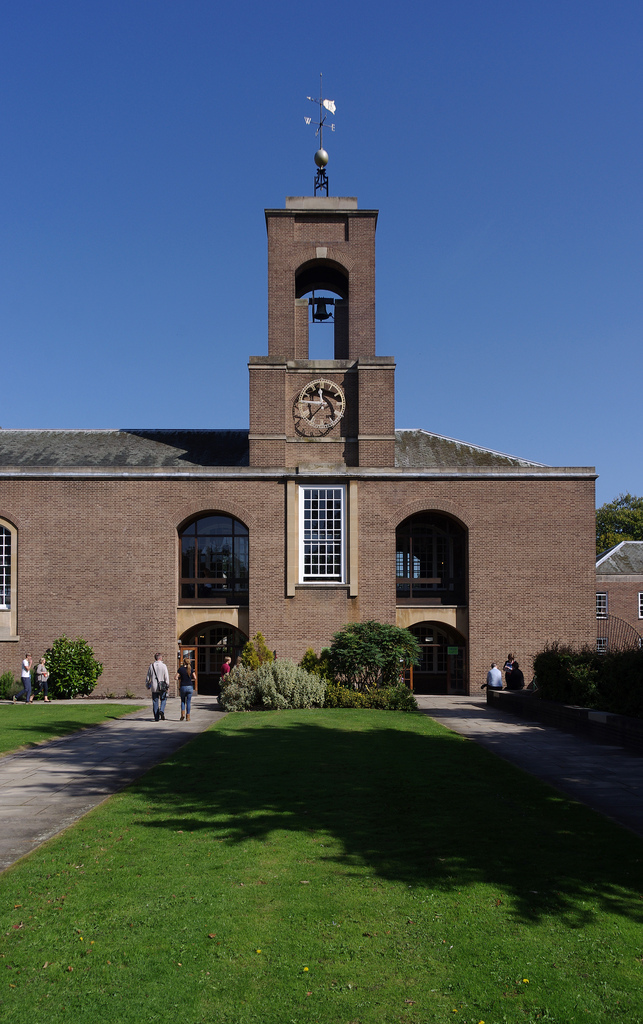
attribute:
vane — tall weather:
[296, 84, 356, 147]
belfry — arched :
[261, 84, 397, 368]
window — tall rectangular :
[298, 488, 359, 568]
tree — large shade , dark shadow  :
[223, 631, 424, 733]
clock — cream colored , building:
[288, 379, 352, 431]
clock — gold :
[293, 377, 359, 431]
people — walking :
[140, 648, 213, 726]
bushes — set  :
[231, 618, 422, 705]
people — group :
[478, 645, 558, 715]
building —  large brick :
[8, 104, 621, 724]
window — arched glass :
[178, 516, 245, 603]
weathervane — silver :
[296, 75, 361, 201]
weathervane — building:
[292, 84, 349, 191]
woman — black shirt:
[175, 654, 208, 731]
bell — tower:
[310, 287, 341, 322]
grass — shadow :
[122, 704, 621, 933]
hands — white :
[298, 382, 327, 400]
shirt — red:
[222, 663, 237, 672]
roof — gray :
[2, 415, 588, 479]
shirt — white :
[18, 655, 34, 678]